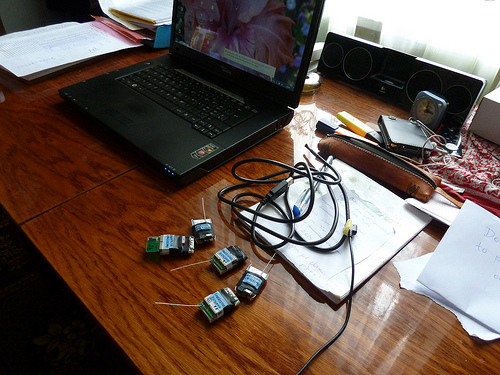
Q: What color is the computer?
A: Black.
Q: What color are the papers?
A: White.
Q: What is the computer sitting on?
A: Desk.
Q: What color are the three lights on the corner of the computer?
A: Blue.